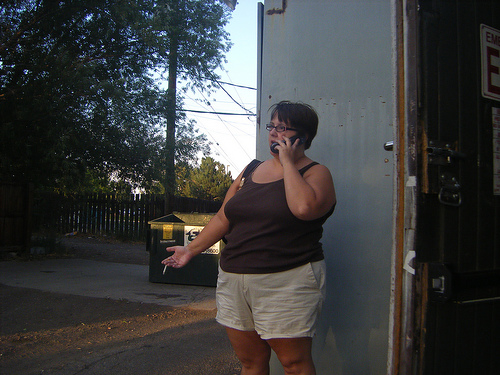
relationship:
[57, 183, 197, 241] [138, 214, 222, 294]
fence behind dumpster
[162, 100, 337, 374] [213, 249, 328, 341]
woman wearing shorts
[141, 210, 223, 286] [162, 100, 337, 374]
dumpster behind woman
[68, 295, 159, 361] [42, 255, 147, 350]
leaves on ground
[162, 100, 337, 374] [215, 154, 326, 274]
woman wearing top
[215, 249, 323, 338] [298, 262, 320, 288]
shorts have a pocket